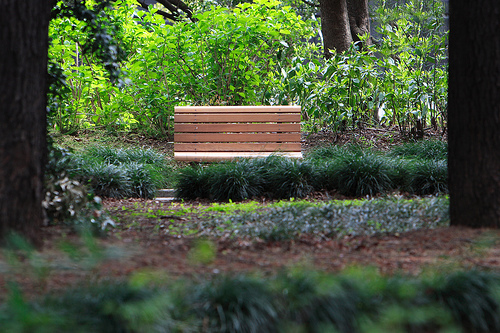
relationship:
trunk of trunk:
[2, 4, 49, 244] [2, 4, 49, 244]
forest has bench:
[0, 6, 499, 314] [174, 102, 308, 161]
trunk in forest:
[2, 4, 49, 244] [0, 6, 499, 314]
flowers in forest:
[155, 202, 450, 238] [0, 6, 499, 314]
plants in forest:
[206, 1, 291, 103] [0, 6, 499, 314]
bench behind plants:
[174, 102, 308, 161] [51, 1, 445, 235]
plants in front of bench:
[73, 160, 443, 195] [174, 102, 308, 161]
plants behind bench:
[51, 1, 445, 235] [174, 102, 308, 161]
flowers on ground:
[155, 202, 450, 238] [9, 127, 496, 327]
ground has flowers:
[9, 127, 496, 327] [155, 202, 450, 238]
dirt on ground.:
[26, 228, 490, 284] [9, 127, 496, 327]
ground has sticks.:
[9, 127, 496, 327] [326, 116, 450, 150]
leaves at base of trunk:
[48, 153, 111, 237] [2, 4, 49, 244]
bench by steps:
[174, 102, 308, 161] [146, 184, 178, 209]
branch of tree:
[43, 0, 212, 26] [7, 2, 192, 238]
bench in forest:
[174, 102, 308, 161] [7, 0, 500, 326]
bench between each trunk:
[174, 102, 308, 161] [2, 4, 49, 244]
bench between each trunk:
[174, 102, 308, 161] [445, 2, 499, 227]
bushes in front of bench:
[71, 163, 449, 211] [174, 102, 308, 161]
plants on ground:
[51, 1, 445, 235] [9, 127, 496, 327]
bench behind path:
[174, 102, 308, 161] [155, 166, 184, 244]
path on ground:
[155, 166, 184, 244] [9, 127, 496, 327]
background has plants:
[13, 0, 497, 142] [206, 1, 291, 103]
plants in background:
[206, 1, 291, 103] [13, 0, 497, 142]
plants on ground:
[206, 1, 291, 103] [9, 127, 496, 327]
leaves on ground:
[211, 217, 487, 278] [9, 127, 496, 327]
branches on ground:
[326, 116, 450, 150] [9, 127, 496, 327]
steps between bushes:
[146, 184, 178, 209] [71, 163, 449, 211]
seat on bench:
[177, 137, 309, 163] [174, 102, 308, 161]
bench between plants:
[174, 102, 308, 161] [206, 1, 291, 103]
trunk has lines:
[2, 4, 49, 244] [18, 16, 48, 109]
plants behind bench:
[206, 1, 291, 103] [174, 102, 308, 161]